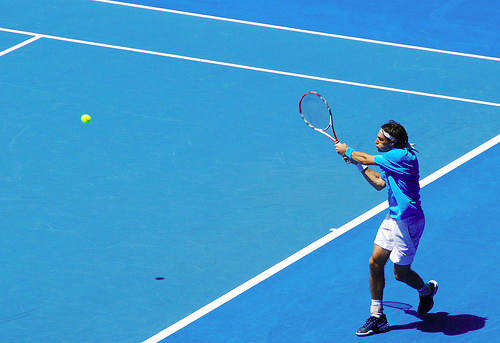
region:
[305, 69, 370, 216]
a tennis player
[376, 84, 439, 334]
a tennis player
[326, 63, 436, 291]
a tennis player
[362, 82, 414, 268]
a tennis player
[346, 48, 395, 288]
a tennis player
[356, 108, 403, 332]
a tennis player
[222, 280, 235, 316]
the line is white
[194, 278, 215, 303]
the line is white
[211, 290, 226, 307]
the line is white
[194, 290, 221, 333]
the line is white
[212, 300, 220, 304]
the line is white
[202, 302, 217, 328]
the line is white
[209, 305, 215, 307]
the line is white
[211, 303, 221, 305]
the line is white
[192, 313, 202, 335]
the line is white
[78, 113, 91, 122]
flying yellow tennis ball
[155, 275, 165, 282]
tennis ball shadow on the court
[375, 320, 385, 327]
blue nike emblem on black shoe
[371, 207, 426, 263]
white shorts on tennis player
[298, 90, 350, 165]
red, white, and blue tennis racket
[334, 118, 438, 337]
man playing tennis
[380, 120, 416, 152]
white headband on tennis player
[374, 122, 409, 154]
concentration on tennis player's face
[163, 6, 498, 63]
white boundary line on tennis court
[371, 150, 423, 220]
blue shirt on tennis player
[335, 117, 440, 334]
Male tennis player hitting ball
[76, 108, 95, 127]
Tennis ball in air in tennis match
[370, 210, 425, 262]
White shorts on male tennis player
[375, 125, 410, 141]
White headband on male tennis player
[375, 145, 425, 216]
Blue shirt on male tennis player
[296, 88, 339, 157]
Red, white, and blue racket held by player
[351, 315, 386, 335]
Blue Nike shoe on male tennis player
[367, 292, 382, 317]
White sock on male tennis player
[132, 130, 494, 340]
White baseline on tennis court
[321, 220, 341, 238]
Center line on tennis court baseline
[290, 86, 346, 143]
A multi-colored tennis racket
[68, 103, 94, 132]
A yellow tennis ball in midair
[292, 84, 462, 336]
A man swinging a tennis racket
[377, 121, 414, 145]
A white headband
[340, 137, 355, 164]
Blue sweat band on a wrist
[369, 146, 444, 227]
turqouise t-shirt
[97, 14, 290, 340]
light blue tennis court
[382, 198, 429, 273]
White pair of shorts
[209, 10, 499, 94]
lines of a tennis court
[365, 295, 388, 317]
white tube sock